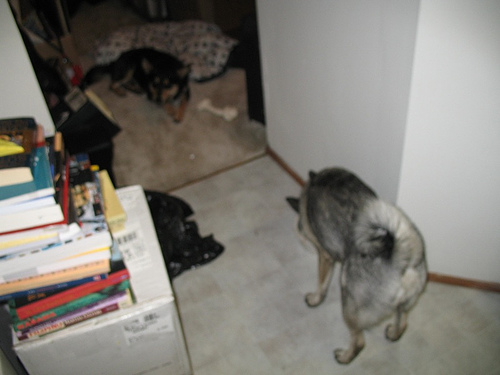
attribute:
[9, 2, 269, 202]
door — open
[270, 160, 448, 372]
dog — downward-looking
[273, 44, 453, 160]
wall — white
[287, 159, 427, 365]
animal — pictured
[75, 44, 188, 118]
animal — pictured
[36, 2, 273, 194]
carpet floor — carpeted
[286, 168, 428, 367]
dog — grey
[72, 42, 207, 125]
dog — black, brown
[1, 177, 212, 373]
box — white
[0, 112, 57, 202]
book — blue